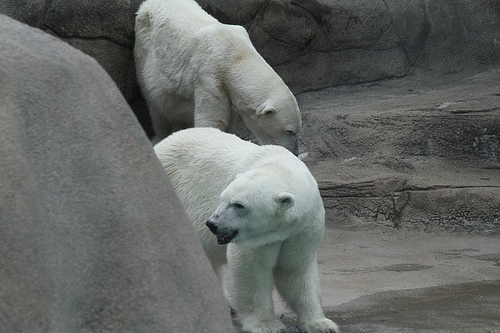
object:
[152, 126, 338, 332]
bear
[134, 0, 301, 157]
bear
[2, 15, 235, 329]
boulder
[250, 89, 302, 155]
head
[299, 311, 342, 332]
foot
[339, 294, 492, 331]
water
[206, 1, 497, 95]
rock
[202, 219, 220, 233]
nose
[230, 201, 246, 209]
eye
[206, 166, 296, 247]
head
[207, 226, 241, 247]
mouth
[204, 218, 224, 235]
bear's nose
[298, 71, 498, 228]
steps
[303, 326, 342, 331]
bear's paw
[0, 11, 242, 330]
rock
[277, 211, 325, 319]
leg